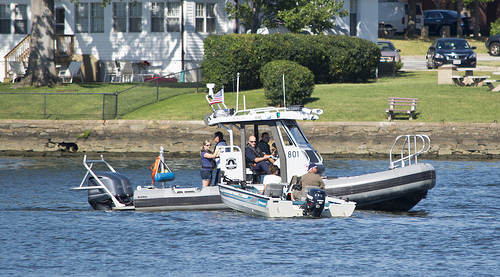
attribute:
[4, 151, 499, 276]
water — blue, calm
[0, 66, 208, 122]
fence — green, linked, black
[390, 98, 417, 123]
bench — small, pink, wooden, brown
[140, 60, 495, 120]
grass — green, cut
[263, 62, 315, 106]
bush — green, large, round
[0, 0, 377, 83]
house — white, large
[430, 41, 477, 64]
car — parked, blue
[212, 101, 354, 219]
boat — filled, small, white, blue, stopped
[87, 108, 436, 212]
boat — large, white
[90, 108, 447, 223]
boats — grouped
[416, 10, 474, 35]
car — black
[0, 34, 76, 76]
rails — wooden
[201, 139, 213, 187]
woman — standing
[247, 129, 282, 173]
men — sitting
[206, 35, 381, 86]
hedges — green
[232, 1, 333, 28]
leaves — green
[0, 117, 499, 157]
wall — beige, stone, brown, white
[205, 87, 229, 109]
flag — american